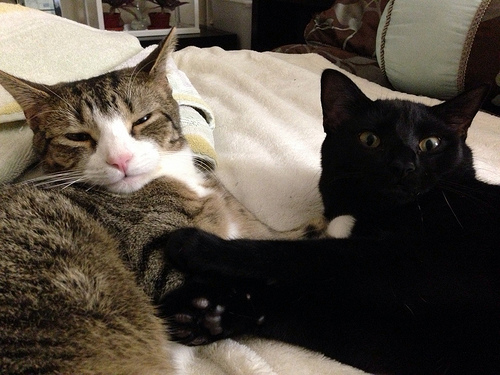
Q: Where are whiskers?
A: On the cat's faces.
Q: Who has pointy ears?
A: The cats.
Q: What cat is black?
A: Cat on right.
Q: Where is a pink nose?
A: On cat's face on the left.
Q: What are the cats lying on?
A: A bed.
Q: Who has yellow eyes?
A: Cat on right.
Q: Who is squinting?
A: Cat on the left.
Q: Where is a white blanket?
A: On the bed.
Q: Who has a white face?
A: Cat on left.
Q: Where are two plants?
A: In two pots.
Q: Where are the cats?
A: On a bed.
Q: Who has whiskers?
A: The cats.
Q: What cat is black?
A: Cat on right.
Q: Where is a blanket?
A: On bed.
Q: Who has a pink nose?
A: Cat on left.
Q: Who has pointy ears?
A: Both cats.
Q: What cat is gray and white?
A: Cat on the left.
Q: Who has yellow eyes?
A: Cat on right.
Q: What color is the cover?
A: White.